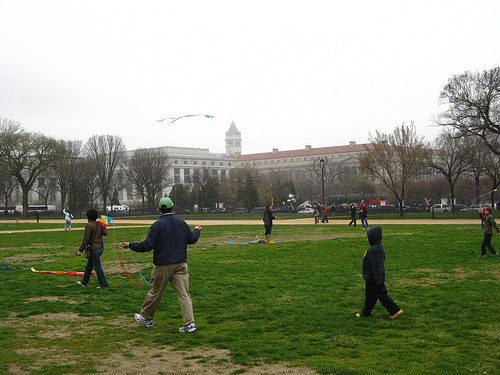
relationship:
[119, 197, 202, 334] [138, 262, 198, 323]
kite flyers with pants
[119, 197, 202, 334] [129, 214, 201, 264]
kite flyers with jacket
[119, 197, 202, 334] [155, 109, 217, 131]
kite flyers helping with kite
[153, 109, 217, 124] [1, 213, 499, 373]
kite on ground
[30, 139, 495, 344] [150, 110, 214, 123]
people flying kites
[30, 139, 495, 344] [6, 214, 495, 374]
people on field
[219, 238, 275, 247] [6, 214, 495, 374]
kite on field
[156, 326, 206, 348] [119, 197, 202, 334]
shoe on kite flyers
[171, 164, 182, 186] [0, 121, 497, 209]
window on building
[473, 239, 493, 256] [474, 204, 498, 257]
leg on boy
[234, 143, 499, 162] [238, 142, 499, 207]
roof on building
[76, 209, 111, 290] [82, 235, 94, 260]
kite flyers with purse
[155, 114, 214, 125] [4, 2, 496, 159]
kite in sky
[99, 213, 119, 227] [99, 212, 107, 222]
kite in hand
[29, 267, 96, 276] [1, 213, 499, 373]
kite on ground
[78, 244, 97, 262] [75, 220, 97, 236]
purse carried over shoulder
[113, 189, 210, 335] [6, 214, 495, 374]
person walking on field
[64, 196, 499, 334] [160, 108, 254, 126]
people flying kites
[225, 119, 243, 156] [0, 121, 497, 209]
buildings on a building